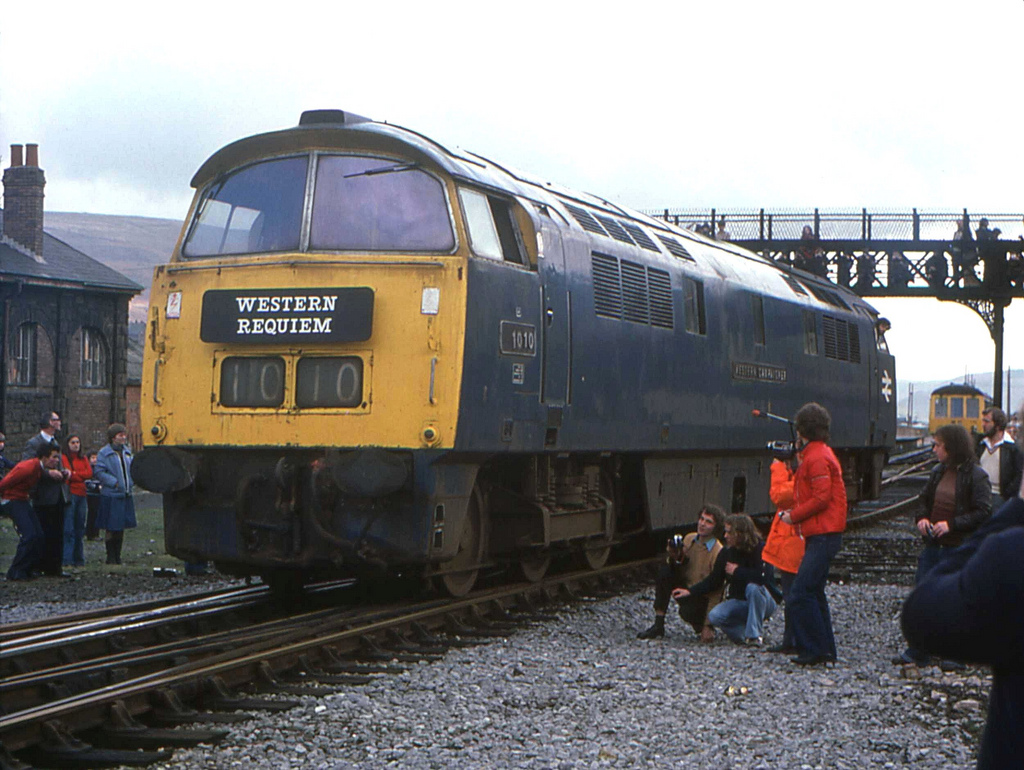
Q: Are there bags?
A: No, there are no bags.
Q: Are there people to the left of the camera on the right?
A: Yes, there is a person to the left of the camera.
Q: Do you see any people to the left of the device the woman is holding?
A: Yes, there is a person to the left of the camera.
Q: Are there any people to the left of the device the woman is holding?
A: Yes, there is a person to the left of the camera.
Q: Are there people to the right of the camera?
A: No, the person is to the left of the camera.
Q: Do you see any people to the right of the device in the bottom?
A: No, the person is to the left of the camera.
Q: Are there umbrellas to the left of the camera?
A: No, there is a person to the left of the camera.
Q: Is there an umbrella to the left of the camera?
A: No, there is a person to the left of the camera.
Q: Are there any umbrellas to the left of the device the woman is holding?
A: No, there is a person to the left of the camera.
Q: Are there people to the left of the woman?
A: Yes, there is a person to the left of the woman.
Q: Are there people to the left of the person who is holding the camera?
A: Yes, there is a person to the left of the woman.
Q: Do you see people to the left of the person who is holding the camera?
A: Yes, there is a person to the left of the woman.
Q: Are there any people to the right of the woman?
A: No, the person is to the left of the woman.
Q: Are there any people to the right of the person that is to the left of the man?
A: No, the person is to the left of the woman.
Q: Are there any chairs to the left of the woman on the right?
A: No, there is a person to the left of the woman.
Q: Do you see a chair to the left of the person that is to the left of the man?
A: No, there is a person to the left of the woman.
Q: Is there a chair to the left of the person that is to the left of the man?
A: No, there is a person to the left of the woman.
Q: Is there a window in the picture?
A: Yes, there is a window.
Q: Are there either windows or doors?
A: Yes, there is a window.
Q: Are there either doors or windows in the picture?
A: Yes, there is a window.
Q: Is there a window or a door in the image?
A: Yes, there is a window.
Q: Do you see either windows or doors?
A: Yes, there is a window.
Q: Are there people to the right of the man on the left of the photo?
A: Yes, there is a person to the right of the man.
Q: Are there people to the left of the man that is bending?
A: No, the person is to the right of the man.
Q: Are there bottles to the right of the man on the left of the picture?
A: No, there is a person to the right of the man.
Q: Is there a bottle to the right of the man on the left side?
A: No, there is a person to the right of the man.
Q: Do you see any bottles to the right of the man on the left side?
A: No, there is a person to the right of the man.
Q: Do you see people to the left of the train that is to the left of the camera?
A: Yes, there is a person to the left of the train.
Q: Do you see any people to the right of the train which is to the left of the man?
A: No, the person is to the left of the train.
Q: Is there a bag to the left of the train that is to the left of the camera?
A: No, there is a person to the left of the train.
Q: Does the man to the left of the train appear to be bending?
A: Yes, the man is bending.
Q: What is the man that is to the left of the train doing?
A: The man is bending.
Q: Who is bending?
A: The man is bending.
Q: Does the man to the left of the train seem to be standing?
A: No, the man is bending.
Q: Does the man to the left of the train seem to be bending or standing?
A: The man is bending.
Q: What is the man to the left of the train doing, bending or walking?
A: The man is bending.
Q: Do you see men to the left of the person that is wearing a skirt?
A: Yes, there is a man to the left of the person.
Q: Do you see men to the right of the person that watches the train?
A: No, the man is to the left of the person.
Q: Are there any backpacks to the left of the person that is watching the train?
A: No, there is a man to the left of the person.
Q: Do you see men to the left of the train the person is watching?
A: Yes, there is a man to the left of the train.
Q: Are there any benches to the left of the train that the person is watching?
A: No, there is a man to the left of the train.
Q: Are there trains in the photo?
A: Yes, there is a train.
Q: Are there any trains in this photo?
A: Yes, there is a train.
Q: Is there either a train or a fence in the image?
A: Yes, there is a train.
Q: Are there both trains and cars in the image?
A: No, there is a train but no cars.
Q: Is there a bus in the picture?
A: No, there are no buses.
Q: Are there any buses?
A: No, there are no buses.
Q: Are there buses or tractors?
A: No, there are no buses or tractors.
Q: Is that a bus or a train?
A: That is a train.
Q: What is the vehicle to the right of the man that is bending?
A: The vehicle is a train.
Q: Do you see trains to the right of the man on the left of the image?
A: Yes, there is a train to the right of the man.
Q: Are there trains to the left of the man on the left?
A: No, the train is to the right of the man.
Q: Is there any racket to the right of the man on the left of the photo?
A: No, there is a train to the right of the man.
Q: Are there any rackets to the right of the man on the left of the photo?
A: No, there is a train to the right of the man.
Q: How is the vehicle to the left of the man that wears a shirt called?
A: The vehicle is a train.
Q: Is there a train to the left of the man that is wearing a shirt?
A: Yes, there is a train to the left of the man.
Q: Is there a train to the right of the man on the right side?
A: No, the train is to the left of the man.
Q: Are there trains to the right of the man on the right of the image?
A: No, the train is to the left of the man.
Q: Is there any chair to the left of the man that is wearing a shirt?
A: No, there is a train to the left of the man.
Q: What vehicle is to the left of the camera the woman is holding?
A: The vehicle is a train.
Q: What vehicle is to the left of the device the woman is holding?
A: The vehicle is a train.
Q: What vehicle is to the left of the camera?
A: The vehicle is a train.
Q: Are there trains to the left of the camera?
A: Yes, there is a train to the left of the camera.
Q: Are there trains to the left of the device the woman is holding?
A: Yes, there is a train to the left of the camera.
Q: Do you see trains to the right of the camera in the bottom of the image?
A: No, the train is to the left of the camera.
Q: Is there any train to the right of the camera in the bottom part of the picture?
A: No, the train is to the left of the camera.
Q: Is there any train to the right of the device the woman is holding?
A: No, the train is to the left of the camera.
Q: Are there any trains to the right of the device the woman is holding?
A: No, the train is to the left of the camera.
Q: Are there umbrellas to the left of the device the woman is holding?
A: No, there is a train to the left of the camera.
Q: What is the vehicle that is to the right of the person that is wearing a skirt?
A: The vehicle is a train.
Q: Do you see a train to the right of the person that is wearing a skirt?
A: Yes, there is a train to the right of the person.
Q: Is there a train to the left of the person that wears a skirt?
A: No, the train is to the right of the person.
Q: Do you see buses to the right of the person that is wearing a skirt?
A: No, there is a train to the right of the person.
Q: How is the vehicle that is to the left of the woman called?
A: The vehicle is a train.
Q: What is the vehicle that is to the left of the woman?
A: The vehicle is a train.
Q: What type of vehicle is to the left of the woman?
A: The vehicle is a train.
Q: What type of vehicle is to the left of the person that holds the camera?
A: The vehicle is a train.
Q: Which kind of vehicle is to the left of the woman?
A: The vehicle is a train.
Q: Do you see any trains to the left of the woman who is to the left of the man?
A: Yes, there is a train to the left of the woman.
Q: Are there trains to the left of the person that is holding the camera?
A: Yes, there is a train to the left of the woman.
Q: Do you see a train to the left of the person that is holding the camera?
A: Yes, there is a train to the left of the woman.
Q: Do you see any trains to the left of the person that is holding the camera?
A: Yes, there is a train to the left of the woman.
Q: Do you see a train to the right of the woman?
A: No, the train is to the left of the woman.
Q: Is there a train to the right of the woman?
A: No, the train is to the left of the woman.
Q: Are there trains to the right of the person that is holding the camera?
A: No, the train is to the left of the woman.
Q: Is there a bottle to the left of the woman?
A: No, there is a train to the left of the woman.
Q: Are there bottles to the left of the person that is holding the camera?
A: No, there is a train to the left of the woman.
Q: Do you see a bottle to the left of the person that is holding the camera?
A: No, there is a train to the left of the woman.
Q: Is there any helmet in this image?
A: No, there are no helmets.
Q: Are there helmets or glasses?
A: No, there are no helmets or glasses.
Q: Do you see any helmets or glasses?
A: No, there are no helmets or glasses.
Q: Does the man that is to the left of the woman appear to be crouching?
A: Yes, the man is crouching.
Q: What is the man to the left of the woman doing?
A: The man is crouching.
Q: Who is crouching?
A: The man is crouching.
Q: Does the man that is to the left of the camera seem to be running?
A: No, the man is crouching.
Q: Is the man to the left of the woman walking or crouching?
A: The man is crouching.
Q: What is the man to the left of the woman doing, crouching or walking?
A: The man is crouching.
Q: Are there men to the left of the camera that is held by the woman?
A: Yes, there is a man to the left of the camera.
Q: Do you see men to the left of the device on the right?
A: Yes, there is a man to the left of the camera.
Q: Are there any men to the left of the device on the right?
A: Yes, there is a man to the left of the camera.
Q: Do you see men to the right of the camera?
A: No, the man is to the left of the camera.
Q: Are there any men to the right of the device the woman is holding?
A: No, the man is to the left of the camera.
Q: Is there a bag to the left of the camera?
A: No, there is a man to the left of the camera.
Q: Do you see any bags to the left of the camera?
A: No, there is a man to the left of the camera.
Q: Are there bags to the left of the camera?
A: No, there is a man to the left of the camera.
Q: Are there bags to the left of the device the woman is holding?
A: No, there is a man to the left of the camera.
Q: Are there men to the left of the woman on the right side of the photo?
A: Yes, there is a man to the left of the woman.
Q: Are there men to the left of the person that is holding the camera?
A: Yes, there is a man to the left of the woman.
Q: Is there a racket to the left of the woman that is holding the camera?
A: No, there is a man to the left of the woman.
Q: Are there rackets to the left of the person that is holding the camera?
A: No, there is a man to the left of the woman.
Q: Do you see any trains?
A: Yes, there is a train.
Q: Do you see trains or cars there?
A: Yes, there is a train.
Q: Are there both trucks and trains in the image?
A: No, there is a train but no trucks.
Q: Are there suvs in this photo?
A: No, there are no suvs.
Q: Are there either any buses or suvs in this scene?
A: No, there are no suvs or buses.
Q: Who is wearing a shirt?
A: The man is wearing a shirt.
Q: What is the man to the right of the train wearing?
A: The man is wearing a shirt.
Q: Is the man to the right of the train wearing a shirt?
A: Yes, the man is wearing a shirt.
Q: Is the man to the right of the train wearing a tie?
A: No, the man is wearing a shirt.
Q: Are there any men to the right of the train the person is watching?
A: Yes, there is a man to the right of the train.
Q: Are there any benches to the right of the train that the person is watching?
A: No, there is a man to the right of the train.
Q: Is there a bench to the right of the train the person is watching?
A: No, there is a man to the right of the train.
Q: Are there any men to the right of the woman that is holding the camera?
A: Yes, there is a man to the right of the woman.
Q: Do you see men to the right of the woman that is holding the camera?
A: Yes, there is a man to the right of the woman.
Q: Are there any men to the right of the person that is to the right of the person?
A: Yes, there is a man to the right of the woman.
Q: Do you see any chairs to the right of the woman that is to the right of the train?
A: No, there is a man to the right of the woman.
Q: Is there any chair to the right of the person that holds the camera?
A: No, there is a man to the right of the woman.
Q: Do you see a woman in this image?
A: Yes, there is a woman.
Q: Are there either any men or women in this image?
A: Yes, there is a woman.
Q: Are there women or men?
A: Yes, there is a woman.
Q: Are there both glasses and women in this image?
A: No, there is a woman but no glasses.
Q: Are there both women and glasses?
A: No, there is a woman but no glasses.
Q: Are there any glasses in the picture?
A: No, there are no glasses.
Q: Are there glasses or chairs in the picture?
A: No, there are no glasses or chairs.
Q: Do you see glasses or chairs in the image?
A: No, there are no glasses or chairs.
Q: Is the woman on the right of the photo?
A: Yes, the woman is on the right of the image.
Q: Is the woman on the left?
A: No, the woman is on the right of the image.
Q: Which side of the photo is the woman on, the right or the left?
A: The woman is on the right of the image.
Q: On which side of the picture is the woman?
A: The woman is on the right of the image.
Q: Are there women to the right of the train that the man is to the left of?
A: Yes, there is a woman to the right of the train.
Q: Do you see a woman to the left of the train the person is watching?
A: No, the woman is to the right of the train.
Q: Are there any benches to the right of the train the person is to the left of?
A: No, there is a woman to the right of the train.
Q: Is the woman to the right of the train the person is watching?
A: Yes, the woman is to the right of the train.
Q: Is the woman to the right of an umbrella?
A: No, the woman is to the right of the train.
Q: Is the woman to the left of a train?
A: No, the woman is to the right of a train.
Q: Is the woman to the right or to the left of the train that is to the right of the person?
A: The woman is to the right of the train.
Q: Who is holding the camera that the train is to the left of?
A: The woman is holding the camera.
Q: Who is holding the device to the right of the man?
A: The woman is holding the camera.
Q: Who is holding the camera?
A: The woman is holding the camera.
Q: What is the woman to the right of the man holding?
A: The woman is holding the camera.